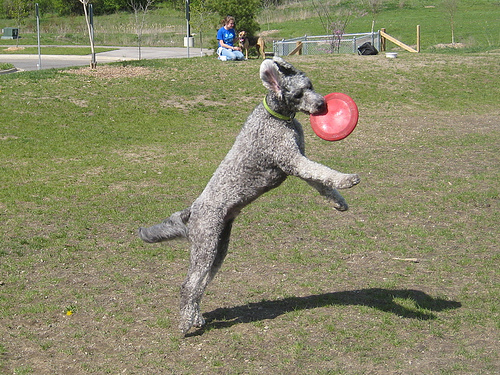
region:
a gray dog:
[136, 58, 357, 336]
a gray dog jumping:
[139, 54, 359, 354]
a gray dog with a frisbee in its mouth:
[135, 54, 360, 336]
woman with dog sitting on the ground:
[211, 14, 254, 68]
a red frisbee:
[308, 88, 361, 144]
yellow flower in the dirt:
[58, 295, 79, 321]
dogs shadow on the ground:
[204, 280, 464, 359]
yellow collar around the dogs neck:
[256, 88, 298, 133]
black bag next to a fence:
[358, 35, 385, 60]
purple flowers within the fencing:
[309, 2, 359, 52]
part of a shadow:
[416, 293, 423, 300]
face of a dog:
[297, 70, 304, 102]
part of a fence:
[67, 85, 88, 112]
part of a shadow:
[333, 286, 345, 310]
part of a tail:
[158, 221, 167, 240]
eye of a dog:
[290, 89, 307, 94]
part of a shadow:
[389, 240, 424, 312]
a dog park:
[13, 9, 492, 363]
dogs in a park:
[140, 6, 388, 343]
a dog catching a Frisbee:
[138, 55, 372, 335]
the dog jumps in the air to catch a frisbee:
[131, 48, 358, 344]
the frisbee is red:
[306, 89, 361, 144]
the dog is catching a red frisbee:
[129, 48, 361, 334]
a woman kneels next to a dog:
[211, 8, 273, 67]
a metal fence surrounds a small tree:
[268, 23, 388, 57]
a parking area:
[6, 29, 206, 76]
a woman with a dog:
[213, 11, 276, 69]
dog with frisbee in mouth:
[135, 55, 392, 345]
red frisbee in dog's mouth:
[303, 90, 363, 147]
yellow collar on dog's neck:
[258, 95, 293, 125]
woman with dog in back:
[213, 15, 270, 64]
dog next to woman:
[236, 29, 272, 60]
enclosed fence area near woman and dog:
[268, 31, 383, 56]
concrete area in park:
[13, 57, 84, 72]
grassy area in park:
[33, 118, 126, 143]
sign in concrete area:
[23, 2, 51, 72]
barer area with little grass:
[51, 341, 137, 369]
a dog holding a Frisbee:
[116, 50, 366, 351]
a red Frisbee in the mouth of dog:
[277, 71, 372, 148]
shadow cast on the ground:
[219, 262, 475, 342]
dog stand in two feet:
[131, 40, 383, 342]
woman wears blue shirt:
[209, 15, 245, 66]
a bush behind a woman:
[196, 0, 274, 62]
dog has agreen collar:
[250, 50, 336, 135]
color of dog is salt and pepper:
[138, 51, 366, 337]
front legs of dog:
[285, 148, 367, 223]